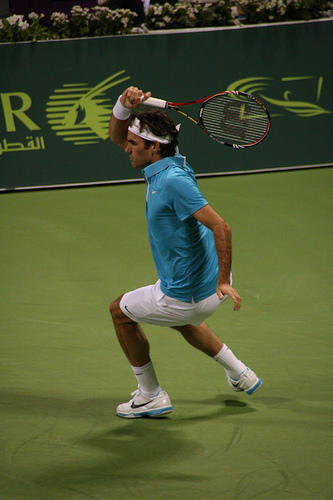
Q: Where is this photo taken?
A: Tennis court.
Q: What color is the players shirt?
A: Blue.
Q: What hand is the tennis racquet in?
A: Right.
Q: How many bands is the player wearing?
A: Two.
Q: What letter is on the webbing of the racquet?
A: W.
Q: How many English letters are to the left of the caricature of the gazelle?
A: One.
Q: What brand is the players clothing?
A: Nike.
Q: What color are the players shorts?
A: White.